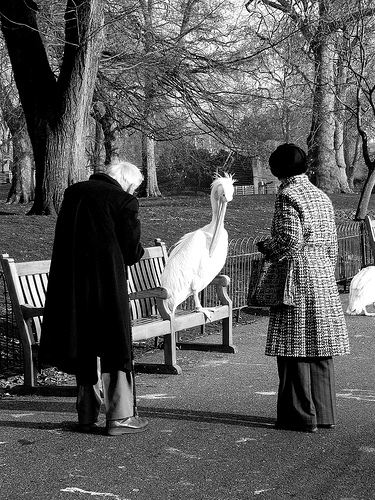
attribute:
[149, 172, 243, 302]
bird — very large and white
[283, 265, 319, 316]
coat — long, black and white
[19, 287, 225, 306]
bench — wooden, Long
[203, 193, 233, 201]
bird — on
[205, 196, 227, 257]
beak — long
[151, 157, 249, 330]
bird — white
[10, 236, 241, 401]
bench — wooden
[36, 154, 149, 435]
man — white haired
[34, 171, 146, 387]
coat — long, black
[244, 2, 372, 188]
tree — tall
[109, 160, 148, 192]
hair — white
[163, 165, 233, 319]
bird — large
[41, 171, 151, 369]
jacket — long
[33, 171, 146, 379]
outerwear — long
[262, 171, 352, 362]
outerwear — long